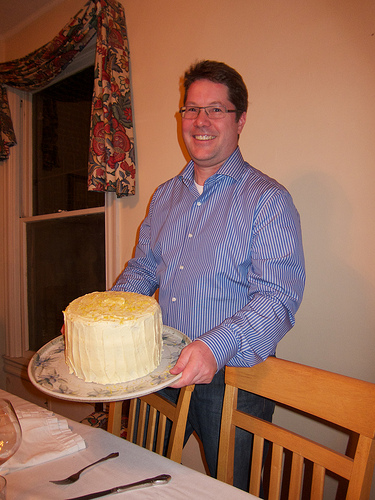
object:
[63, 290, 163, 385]
cake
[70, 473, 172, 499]
butter knife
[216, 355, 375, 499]
chair back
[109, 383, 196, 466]
chair back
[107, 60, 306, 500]
man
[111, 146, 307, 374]
shirt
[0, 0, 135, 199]
curtain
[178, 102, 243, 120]
glasses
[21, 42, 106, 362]
window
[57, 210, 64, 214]
lock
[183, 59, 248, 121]
hair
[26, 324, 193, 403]
design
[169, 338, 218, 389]
left hand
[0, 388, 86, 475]
napkin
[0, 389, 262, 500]
table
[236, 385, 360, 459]
opening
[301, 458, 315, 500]
opening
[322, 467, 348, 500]
opening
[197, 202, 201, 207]
button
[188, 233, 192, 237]
button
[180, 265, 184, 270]
button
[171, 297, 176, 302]
button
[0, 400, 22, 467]
glass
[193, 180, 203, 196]
t shirt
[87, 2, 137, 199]
right side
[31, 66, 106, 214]
pane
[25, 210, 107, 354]
pane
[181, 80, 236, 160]
face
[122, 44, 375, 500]
shadow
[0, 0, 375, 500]
wall